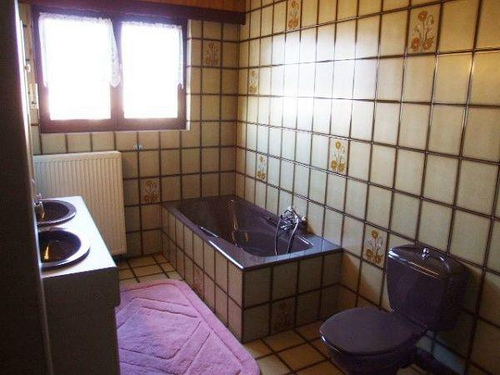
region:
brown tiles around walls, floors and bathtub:
[6, 5, 491, 367]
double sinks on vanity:
[35, 160, 120, 365]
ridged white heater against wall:
[30, 145, 120, 255]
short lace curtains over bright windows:
[35, 5, 185, 120]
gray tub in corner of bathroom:
[165, 185, 335, 300]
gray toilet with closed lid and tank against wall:
[315, 240, 450, 360]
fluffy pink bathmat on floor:
[115, 271, 255, 367]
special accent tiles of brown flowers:
[321, 135, 351, 171]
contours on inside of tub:
[197, 196, 307, 256]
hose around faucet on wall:
[270, 205, 306, 256]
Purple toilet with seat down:
[317, 238, 475, 373]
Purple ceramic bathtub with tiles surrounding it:
[152, 178, 342, 335]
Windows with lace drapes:
[30, 7, 194, 132]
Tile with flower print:
[317, 130, 357, 180]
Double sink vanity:
[22, 162, 127, 310]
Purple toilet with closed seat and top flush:
[325, 234, 470, 373]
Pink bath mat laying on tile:
[105, 258, 261, 373]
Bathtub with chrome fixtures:
[151, 180, 345, 338]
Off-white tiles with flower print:
[320, 128, 354, 181]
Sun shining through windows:
[33, 3, 195, 135]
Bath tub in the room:
[161, 180, 323, 295]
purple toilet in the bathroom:
[322, 226, 466, 357]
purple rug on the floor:
[125, 279, 227, 374]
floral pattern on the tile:
[325, 140, 350, 172]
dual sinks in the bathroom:
[39, 184, 89, 280]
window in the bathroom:
[30, 8, 197, 142]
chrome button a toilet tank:
[418, 236, 430, 258]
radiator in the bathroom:
[35, 152, 137, 280]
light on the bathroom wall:
[25, 77, 41, 118]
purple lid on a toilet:
[319, 294, 429, 366]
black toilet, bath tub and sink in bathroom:
[5, 1, 473, 361]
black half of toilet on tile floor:
[314, 300, 432, 374]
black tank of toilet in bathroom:
[374, 230, 465, 327]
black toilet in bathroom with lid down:
[316, 228, 489, 367]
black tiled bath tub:
[162, 182, 349, 342]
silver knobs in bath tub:
[272, 189, 308, 254]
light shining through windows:
[37, 5, 191, 127]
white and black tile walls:
[194, 6, 493, 241]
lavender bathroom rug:
[117, 277, 256, 371]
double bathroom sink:
[28, 182, 124, 308]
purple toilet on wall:
[292, 196, 473, 371]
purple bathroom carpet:
[61, 240, 267, 365]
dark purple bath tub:
[149, 145, 330, 302]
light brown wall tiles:
[360, 87, 487, 211]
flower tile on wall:
[315, 127, 357, 182]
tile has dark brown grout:
[371, 97, 487, 229]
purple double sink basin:
[33, 173, 95, 321]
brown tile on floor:
[257, 328, 317, 372]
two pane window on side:
[23, 10, 208, 150]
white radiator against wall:
[26, 136, 192, 317]